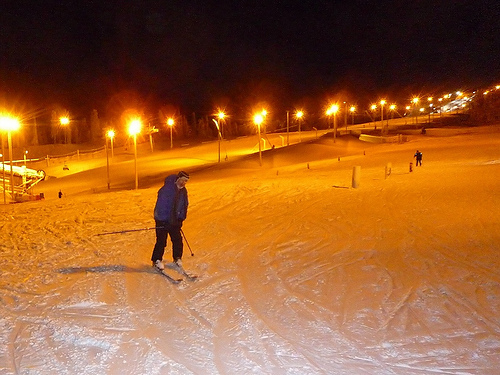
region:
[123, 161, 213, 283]
Man on a ski slope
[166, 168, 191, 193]
man wearing a knit hat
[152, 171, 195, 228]
man wearing a blue jacket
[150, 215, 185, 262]
man wearing black pants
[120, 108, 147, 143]
lights on a pole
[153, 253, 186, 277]
man wearing snow boots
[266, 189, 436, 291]
tracks in the snow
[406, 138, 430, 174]
person skiing down the slope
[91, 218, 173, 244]
man holding a ski pole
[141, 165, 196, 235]
man wearing a snow jacket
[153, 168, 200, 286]
a man is on skis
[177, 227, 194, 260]
pole is in a man's hand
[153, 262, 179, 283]
ski is on a man's foot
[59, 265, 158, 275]
shadow of a man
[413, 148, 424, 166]
a person at a distance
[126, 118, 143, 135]
light is on a pole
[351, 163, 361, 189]
a post in the snow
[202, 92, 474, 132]
a large section of lights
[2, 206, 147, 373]
there are tracks in the snow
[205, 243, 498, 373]
there are tracks in the snow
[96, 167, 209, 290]
person skiing down hill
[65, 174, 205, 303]
person skiing on snow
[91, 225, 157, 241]
red ski poles in hand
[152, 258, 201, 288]
white skis on feet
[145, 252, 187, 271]
white ski shoes on feet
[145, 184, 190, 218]
purple ski jacket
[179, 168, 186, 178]
black hat on head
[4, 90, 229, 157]
bright orange lights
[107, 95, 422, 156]
line of light poles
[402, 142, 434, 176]
person skiing down hill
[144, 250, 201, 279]
Person standing on skis.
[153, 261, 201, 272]
Person wearing white boots.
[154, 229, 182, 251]
Person wearing black pants.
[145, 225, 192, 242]
Person holding ski poles.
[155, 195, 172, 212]
Person wearing blue jacket.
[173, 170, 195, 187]
Hat on person's head.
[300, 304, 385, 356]
Ground is covered with snow.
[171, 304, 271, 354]
Snow on ground is white.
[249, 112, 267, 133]
Light illuminated on top of pole.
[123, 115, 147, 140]
Light illuminated on top of pole.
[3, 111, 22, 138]
the bright orange light on the ski slope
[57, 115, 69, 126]
the bright orange light on the ski slope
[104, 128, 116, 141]
the bright orange light on the ski slope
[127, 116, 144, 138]
the bright orange light on the ski slope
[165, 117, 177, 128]
the bright orange light on the ski slope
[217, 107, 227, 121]
the bright orange light on the ski slope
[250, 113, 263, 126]
the bright orange light on the ski slope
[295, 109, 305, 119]
the bright orange light on the ski slope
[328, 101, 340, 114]
the bright orange light on the ski slope